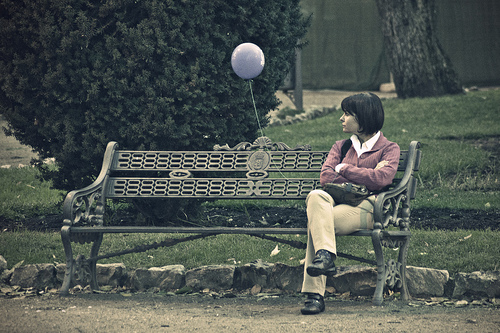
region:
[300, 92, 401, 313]
a woman sitting on a park bench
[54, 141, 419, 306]
a metal park bench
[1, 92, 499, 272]
a grassy area behind the bench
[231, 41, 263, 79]
a purple balloon behind the bench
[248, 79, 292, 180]
a string attached to the balloon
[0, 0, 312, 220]
a large bush behind the bench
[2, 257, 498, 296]
rocks lined up in a row behind the bench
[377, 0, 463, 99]
a tree trunk behind the woman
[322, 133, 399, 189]
a red sweater on the woman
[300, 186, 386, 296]
brown pants on the woman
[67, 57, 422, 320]
woman is sitting on the bench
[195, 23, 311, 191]
the balloon is purple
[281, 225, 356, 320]
the shoes are black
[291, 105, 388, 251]
a bag on woman's lap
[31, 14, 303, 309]
a bush behind the bench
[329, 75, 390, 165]
woman's hair is short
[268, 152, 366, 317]
the pants are brown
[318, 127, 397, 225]
the woman is wearing a blazer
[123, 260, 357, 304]
rocks under the bench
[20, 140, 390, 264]
the bench is green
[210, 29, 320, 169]
this is a balloom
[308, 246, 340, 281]
this is the right shoe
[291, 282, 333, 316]
this is the left shoe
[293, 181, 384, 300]
these are brown pants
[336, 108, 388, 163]
the white under shirt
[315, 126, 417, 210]
this is a pink shirt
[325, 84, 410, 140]
this is black hair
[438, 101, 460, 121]
this is the grass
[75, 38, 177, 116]
these are the leaves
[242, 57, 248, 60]
this is the color purple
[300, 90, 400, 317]
Woman sitting on metal bench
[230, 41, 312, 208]
Purple balloon by woman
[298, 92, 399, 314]
Woman wearing purple jacket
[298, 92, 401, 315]
Woman wearing beige pants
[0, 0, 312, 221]
Large green tree behind metal bench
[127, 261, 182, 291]
Large rock behind bench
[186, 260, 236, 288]
Large rock behind bench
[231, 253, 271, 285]
Rock behind bench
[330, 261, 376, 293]
Rock behind bench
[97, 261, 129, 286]
Rock behind bench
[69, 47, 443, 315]
the woman in the park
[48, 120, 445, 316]
the woman on the bench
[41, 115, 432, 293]
the woman is sitting down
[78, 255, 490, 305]
the stones behind the bench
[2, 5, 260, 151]
the thick green bush behind the bench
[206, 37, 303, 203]
the balloon tied to the bench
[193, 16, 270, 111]
the balloon is purple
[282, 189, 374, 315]
the leg is crossed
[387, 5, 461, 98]
the tree trunk behind the woman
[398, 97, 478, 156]
the low green grass behind the woman